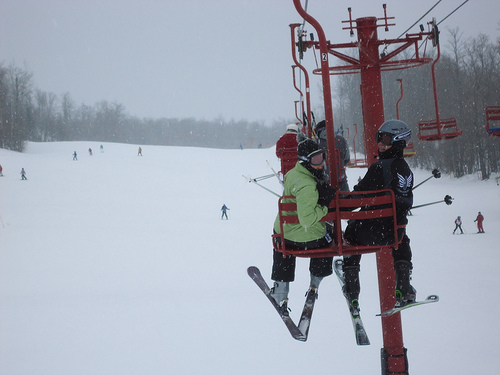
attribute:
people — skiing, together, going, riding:
[229, 116, 421, 251]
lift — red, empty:
[229, 187, 430, 282]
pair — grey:
[352, 108, 409, 156]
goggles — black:
[369, 126, 407, 145]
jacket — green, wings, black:
[256, 162, 344, 238]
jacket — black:
[325, 139, 445, 238]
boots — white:
[312, 230, 455, 314]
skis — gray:
[317, 290, 441, 366]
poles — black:
[422, 165, 467, 205]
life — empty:
[417, 105, 469, 138]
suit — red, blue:
[257, 136, 310, 180]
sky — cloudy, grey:
[62, 25, 207, 100]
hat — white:
[255, 114, 315, 144]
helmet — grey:
[363, 105, 424, 143]